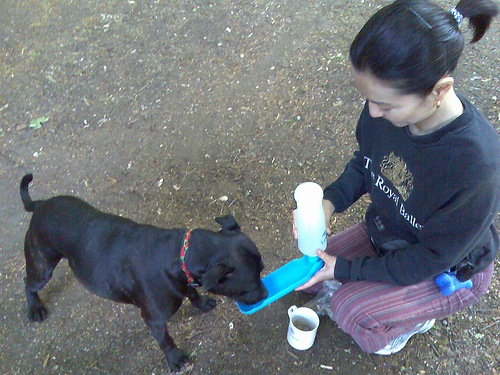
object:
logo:
[377, 150, 417, 202]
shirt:
[321, 101, 498, 287]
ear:
[432, 67, 457, 107]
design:
[359, 146, 428, 233]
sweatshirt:
[302, 99, 496, 289]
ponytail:
[425, 1, 487, 43]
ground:
[472, 138, 490, 176]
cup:
[280, 301, 320, 349]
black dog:
[19, 172, 268, 373]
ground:
[1, 0, 498, 373]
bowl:
[235, 260, 317, 317]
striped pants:
[312, 221, 497, 359]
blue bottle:
[290, 183, 329, 258]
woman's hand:
[297, 248, 338, 291]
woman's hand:
[287, 197, 338, 240]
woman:
[290, 1, 499, 356]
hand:
[290, 210, 330, 235]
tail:
[5, 158, 64, 228]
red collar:
[177, 229, 188, 279]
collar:
[179, 229, 194, 291]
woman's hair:
[351, 7, 486, 110]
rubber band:
[446, 4, 478, 46]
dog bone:
[434, 270, 474, 297]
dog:
[14, 173, 265, 365]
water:
[268, 263, 316, 298]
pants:
[324, 218, 494, 353]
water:
[293, 315, 314, 330]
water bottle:
[234, 177, 329, 316]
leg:
[139, 304, 195, 374]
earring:
[436, 98, 443, 108]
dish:
[234, 250, 323, 314]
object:
[436, 273, 478, 299]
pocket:
[428, 256, 483, 299]